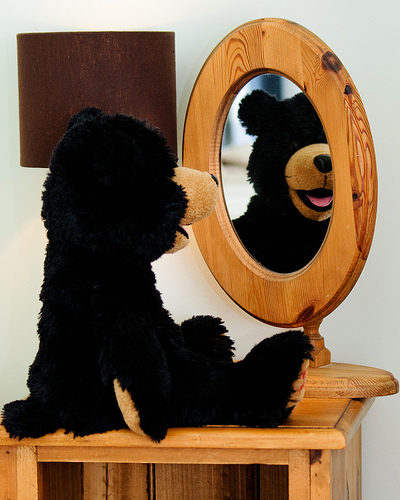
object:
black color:
[54, 161, 114, 305]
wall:
[0, 0, 399, 499]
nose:
[207, 172, 220, 186]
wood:
[109, 425, 342, 470]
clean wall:
[7, 0, 400, 17]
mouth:
[293, 185, 336, 213]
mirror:
[218, 68, 336, 282]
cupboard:
[0, 397, 380, 499]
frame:
[180, 18, 380, 330]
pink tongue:
[304, 193, 334, 209]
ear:
[237, 86, 278, 138]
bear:
[2, 106, 314, 441]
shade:
[17, 27, 179, 169]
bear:
[229, 89, 331, 274]